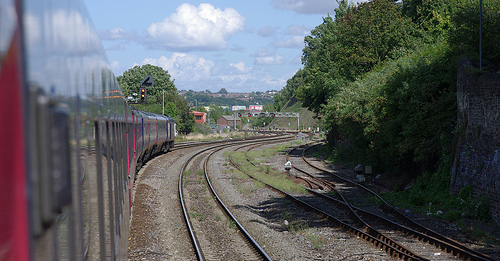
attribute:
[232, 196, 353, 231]
shade — pictured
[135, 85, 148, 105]
lights — red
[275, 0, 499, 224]
shrubs — leafy, green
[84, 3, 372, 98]
clouds — white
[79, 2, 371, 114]
sky — blue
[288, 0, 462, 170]
tree — leafy, green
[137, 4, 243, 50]
clouds — different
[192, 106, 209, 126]
building — red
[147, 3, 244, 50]
cloud — part, white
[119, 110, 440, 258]
track — curving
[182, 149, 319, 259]
rails — several, train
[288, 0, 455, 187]
trees — pictured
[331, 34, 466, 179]
shrubbery — green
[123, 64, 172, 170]
traffic light — small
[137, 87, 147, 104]
light — train, traffic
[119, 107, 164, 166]
doorways — red